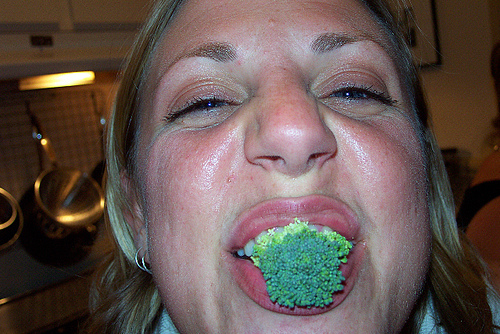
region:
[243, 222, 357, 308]
A broccoli floret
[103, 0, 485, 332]
A lady with a broccoli floret in her mouth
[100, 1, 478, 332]
A blond hair person with food in their mouth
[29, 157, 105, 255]
A large pot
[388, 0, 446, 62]
A painting on the wall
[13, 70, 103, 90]
A light affixed to the wall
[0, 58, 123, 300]
A peg board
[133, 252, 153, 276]
A earring in a woman's ear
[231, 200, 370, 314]
A persons lip wrapped around a broccoli floret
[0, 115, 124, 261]
Cooking tools on a peg board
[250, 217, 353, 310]
the broccoli in the woman's mouth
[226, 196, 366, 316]
the lips on the woman's mouth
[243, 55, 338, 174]
the nose on the woman's face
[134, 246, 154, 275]
the earrings in the woman's earlobe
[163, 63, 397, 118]
the eyes on the woman's face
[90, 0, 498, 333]
the hair on the woman's head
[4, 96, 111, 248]
the pots hanging in the back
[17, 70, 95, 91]
the turned on light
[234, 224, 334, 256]
the teeth in the woman's mouth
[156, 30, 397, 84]
the eyes on the woman's face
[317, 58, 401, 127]
left eye of the girl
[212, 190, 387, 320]
broccoli in girl's mouth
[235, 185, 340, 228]
top lip of the girl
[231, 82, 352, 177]
nose on the girl's face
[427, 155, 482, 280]
light hair of the girl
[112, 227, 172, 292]
earrings in girl's ear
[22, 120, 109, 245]
pan in the background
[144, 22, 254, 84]
eyebrow of the girl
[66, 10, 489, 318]
woman looking at the camera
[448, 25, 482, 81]
wall in the background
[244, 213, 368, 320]
green broccoli in girl's mouth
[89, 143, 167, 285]
blonde hair on woman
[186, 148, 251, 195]
oily skin on woman eating broccoli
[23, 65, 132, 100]
light in background on left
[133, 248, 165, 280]
two small metal earrings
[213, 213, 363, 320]
red lips on woman eating broccoli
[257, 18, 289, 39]
small pimples on woman's face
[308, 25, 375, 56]
neatly trimmed eyebrow on woman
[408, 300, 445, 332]
white collar on woman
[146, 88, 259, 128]
squinted eyes of woman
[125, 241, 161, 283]
the earring is silver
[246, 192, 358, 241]
the lips are red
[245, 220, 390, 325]
the vegetable is broccoli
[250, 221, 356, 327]
the broccoli is green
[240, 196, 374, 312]
the broccoli in mouth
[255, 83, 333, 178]
the nose is red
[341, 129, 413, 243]
the cheeks are red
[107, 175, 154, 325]
the hair is blonde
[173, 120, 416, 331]
the lady has acne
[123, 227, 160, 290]
earring is double hooped